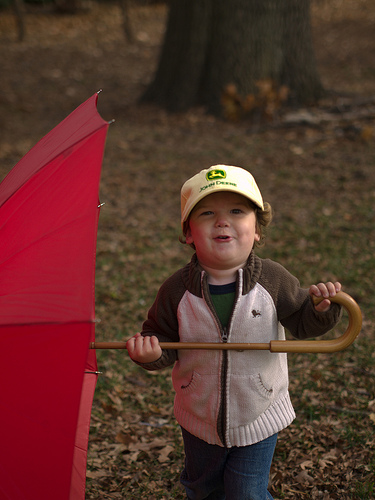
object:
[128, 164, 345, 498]
boy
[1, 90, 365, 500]
umbrella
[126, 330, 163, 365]
hand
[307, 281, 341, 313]
hand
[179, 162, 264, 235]
hat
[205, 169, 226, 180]
deer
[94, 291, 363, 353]
handle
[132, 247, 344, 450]
sweater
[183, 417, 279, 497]
jeans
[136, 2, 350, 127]
tree trunk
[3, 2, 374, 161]
background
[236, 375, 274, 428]
pocket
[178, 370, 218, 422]
pocket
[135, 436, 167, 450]
leaf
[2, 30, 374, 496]
ground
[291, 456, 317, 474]
leaf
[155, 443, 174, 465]
leaf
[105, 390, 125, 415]
leaf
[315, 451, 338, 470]
leaf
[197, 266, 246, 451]
zip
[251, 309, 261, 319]
design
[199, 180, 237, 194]
text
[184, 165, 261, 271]
head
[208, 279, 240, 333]
shirt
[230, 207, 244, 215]
eye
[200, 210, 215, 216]
eye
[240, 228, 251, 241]
dimple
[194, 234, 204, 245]
dimple